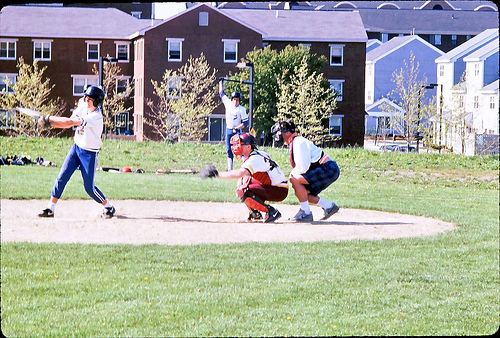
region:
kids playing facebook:
[64, 29, 494, 328]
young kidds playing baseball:
[33, 31, 449, 313]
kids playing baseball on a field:
[18, 22, 350, 330]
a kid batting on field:
[25, 35, 215, 249]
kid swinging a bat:
[2, 50, 207, 288]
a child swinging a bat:
[15, 55, 151, 295]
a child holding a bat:
[11, 37, 128, 216]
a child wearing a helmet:
[28, 32, 162, 235]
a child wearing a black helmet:
[29, 49, 179, 282]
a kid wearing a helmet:
[22, 47, 149, 212]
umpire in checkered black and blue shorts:
[273, 115, 345, 221]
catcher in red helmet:
[203, 127, 289, 227]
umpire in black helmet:
[275, 119, 312, 165]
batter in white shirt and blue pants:
[10, 71, 125, 223]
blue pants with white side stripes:
[42, 135, 112, 222]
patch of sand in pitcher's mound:
[8, 177, 450, 262]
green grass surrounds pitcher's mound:
[0, 162, 497, 334]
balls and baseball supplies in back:
[2, 151, 222, 181]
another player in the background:
[209, 75, 249, 161]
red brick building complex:
[0, 0, 364, 144]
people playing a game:
[58, 61, 352, 215]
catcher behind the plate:
[211, 131, 278, 199]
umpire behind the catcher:
[283, 103, 343, 190]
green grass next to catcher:
[241, 264, 274, 295]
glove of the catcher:
[192, 158, 226, 197]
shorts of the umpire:
[293, 154, 343, 196]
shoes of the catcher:
[259, 202, 282, 232]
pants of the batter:
[47, 156, 129, 206]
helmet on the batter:
[81, 80, 111, 111]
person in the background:
[203, 75, 254, 133]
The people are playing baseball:
[7, 52, 427, 242]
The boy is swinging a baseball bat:
[15, 66, 66, 146]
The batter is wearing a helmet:
[50, 60, 121, 120]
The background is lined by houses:
[16, 9, 493, 124]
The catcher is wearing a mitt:
[183, 120, 292, 237]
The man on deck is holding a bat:
[200, 53, 259, 165]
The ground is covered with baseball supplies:
[7, 145, 225, 181]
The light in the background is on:
[217, 40, 273, 93]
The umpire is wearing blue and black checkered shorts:
[295, 160, 355, 197]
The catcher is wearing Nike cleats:
[263, 207, 288, 230]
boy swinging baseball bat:
[15, 80, 115, 215]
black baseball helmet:
[80, 75, 105, 105]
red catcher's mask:
[230, 125, 250, 155]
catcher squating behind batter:
[195, 130, 285, 225]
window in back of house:
[165, 30, 180, 60]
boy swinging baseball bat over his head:
[200, 71, 255, 127]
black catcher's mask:
[266, 115, 296, 150]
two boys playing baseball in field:
[190, 115, 350, 225]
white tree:
[140, 46, 220, 141]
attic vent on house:
[196, 8, 213, 27]